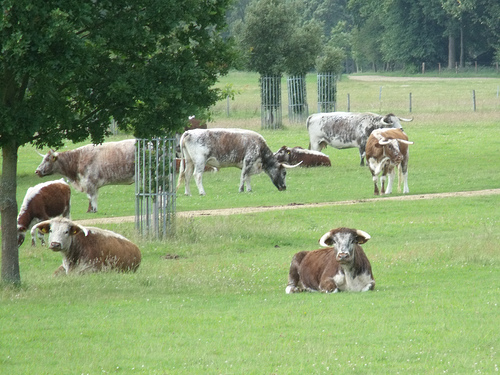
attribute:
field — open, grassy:
[1, 64, 481, 373]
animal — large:
[364, 123, 415, 195]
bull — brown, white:
[176, 128, 293, 192]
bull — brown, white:
[362, 126, 413, 191]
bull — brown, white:
[284, 227, 379, 294]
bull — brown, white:
[31, 213, 139, 268]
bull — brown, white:
[37, 138, 137, 208]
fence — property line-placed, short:
[192, 73, 498, 123]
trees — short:
[237, 5, 344, 134]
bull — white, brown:
[284, 223, 384, 299]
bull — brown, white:
[28, 210, 144, 278]